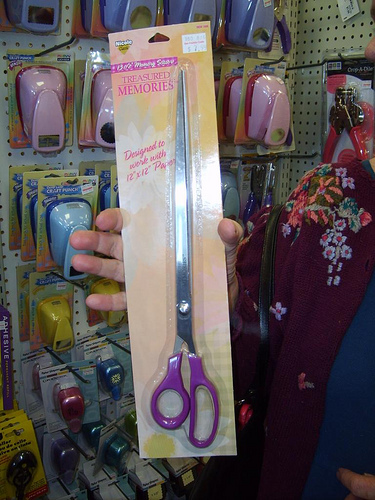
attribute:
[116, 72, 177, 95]
letters — pink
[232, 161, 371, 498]
sweater — purple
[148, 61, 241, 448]
scissors — purple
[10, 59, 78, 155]
item — pink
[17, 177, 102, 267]
product — blue